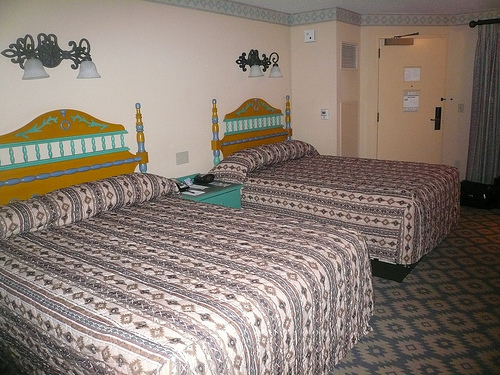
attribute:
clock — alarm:
[196, 167, 221, 191]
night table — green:
[168, 167, 255, 214]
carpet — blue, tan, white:
[324, 202, 499, 372]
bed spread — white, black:
[0, 171, 375, 373]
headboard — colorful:
[3, 102, 148, 208]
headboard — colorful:
[212, 95, 290, 158]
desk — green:
[179, 174, 241, 209]